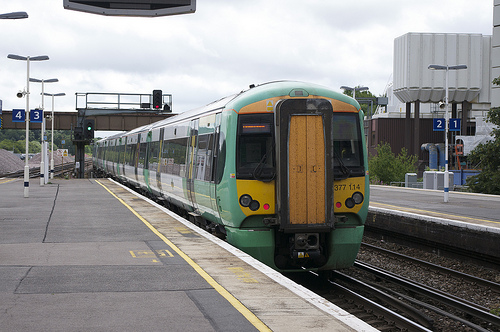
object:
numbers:
[329, 182, 362, 194]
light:
[428, 62, 468, 71]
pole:
[443, 73, 452, 204]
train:
[84, 80, 372, 274]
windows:
[93, 132, 217, 183]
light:
[239, 193, 261, 212]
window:
[235, 111, 275, 182]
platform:
[366, 184, 500, 237]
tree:
[461, 76, 500, 195]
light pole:
[7, 51, 50, 198]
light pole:
[28, 76, 60, 186]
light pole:
[40, 92, 65, 182]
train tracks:
[299, 239, 498, 330]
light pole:
[425, 63, 469, 202]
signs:
[431, 116, 461, 135]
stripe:
[91, 177, 272, 330]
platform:
[1, 176, 381, 331]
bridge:
[0, 92, 178, 131]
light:
[261, 202, 271, 212]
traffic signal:
[80, 115, 94, 143]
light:
[87, 126, 93, 130]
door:
[288, 115, 326, 225]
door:
[185, 127, 200, 214]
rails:
[297, 239, 499, 330]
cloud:
[0, 1, 493, 111]